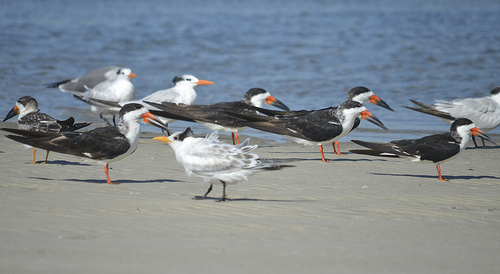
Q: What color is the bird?
A: White and black.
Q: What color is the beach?
A: Gray.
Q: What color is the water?
A: Blue.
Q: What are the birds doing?
A: Standing.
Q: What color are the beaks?
A: Black and orange.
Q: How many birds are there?
A: Eleven.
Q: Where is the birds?
A: On the beach.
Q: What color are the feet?
A: Orange.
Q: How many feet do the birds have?
A: Two.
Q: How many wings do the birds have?
A: Two.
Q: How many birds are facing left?
A: 2.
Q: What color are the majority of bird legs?
A: Orange.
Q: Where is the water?
A: Behind the birds.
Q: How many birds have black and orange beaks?
A: 6.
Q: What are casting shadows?
A: The birds.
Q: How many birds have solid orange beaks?
A: 3.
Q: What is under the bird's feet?
A: Sand.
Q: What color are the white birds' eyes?
A: Black.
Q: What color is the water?
A: Blue.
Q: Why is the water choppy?
A: It's windy.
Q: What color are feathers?
A: Black.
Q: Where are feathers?
A: On neck.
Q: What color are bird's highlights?
A: White.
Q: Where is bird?
A: In sand.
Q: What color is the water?
A: Blue.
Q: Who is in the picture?
A: Birds.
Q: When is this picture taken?
A: Daytime.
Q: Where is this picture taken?
A: Beach.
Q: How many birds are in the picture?
A: Eleven.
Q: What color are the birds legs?
A: Orange.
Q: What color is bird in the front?
A: White.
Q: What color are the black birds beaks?
A: Orange and black.